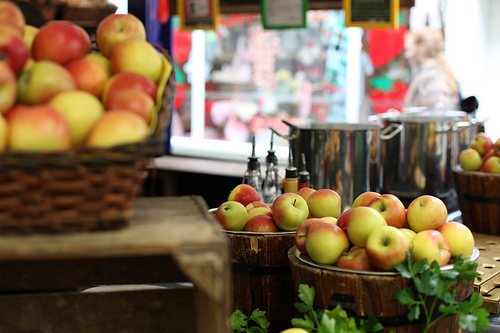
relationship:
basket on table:
[0, 145, 153, 232] [0, 197, 229, 331]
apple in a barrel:
[307, 223, 345, 264] [290, 267, 420, 309]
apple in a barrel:
[366, 227, 406, 267] [290, 267, 420, 309]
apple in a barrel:
[342, 249, 367, 266] [290, 267, 420, 309]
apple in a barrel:
[347, 208, 384, 226] [290, 267, 420, 309]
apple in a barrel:
[407, 195, 447, 230] [290, 267, 420, 309]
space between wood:
[98, 277, 183, 292] [55, 243, 196, 321]